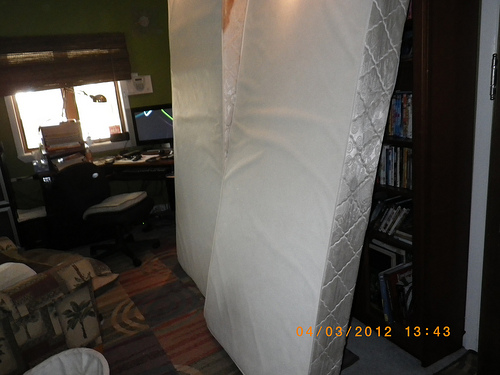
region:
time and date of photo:
[293, 325, 456, 340]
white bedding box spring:
[218, 0, 385, 314]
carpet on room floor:
[122, 297, 196, 367]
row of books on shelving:
[379, 146, 413, 186]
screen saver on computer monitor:
[132, 104, 175, 141]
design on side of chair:
[60, 296, 95, 345]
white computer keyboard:
[107, 163, 168, 178]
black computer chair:
[63, 162, 163, 274]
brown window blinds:
[0, 36, 132, 82]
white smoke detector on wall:
[125, 6, 160, 33]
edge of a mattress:
[362, 142, 372, 216]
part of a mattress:
[253, 212, 266, 247]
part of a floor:
[163, 307, 183, 348]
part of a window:
[98, 95, 113, 123]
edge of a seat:
[48, 250, 61, 294]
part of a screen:
[133, 113, 148, 121]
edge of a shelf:
[428, 250, 437, 289]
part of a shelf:
[386, 221, 408, 255]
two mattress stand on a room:
[155, 0, 410, 371]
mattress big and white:
[155, 0, 415, 371]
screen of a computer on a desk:
[117, 95, 172, 151]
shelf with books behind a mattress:
[350, 0, 480, 355]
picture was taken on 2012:
[211, 200, 498, 373]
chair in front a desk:
[2, 156, 64, 252]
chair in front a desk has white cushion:
[48, 156, 165, 271]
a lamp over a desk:
[54, 80, 114, 119]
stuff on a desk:
[97, 141, 150, 165]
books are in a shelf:
[374, 97, 413, 334]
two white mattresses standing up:
[110, 6, 447, 373]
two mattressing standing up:
[132, 25, 450, 371]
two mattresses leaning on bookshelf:
[121, 12, 497, 302]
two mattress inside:
[107, 23, 457, 373]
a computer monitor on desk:
[102, 90, 229, 184]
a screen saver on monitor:
[112, 91, 210, 163]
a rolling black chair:
[53, 145, 178, 277]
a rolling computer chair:
[37, 150, 183, 273]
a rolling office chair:
[44, 152, 174, 267]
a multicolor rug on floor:
[54, 222, 246, 373]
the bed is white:
[229, 182, 321, 267]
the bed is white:
[192, 167, 286, 241]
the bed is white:
[259, 202, 304, 266]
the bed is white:
[242, 154, 290, 219]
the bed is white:
[246, 135, 290, 193]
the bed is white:
[219, 134, 251, 174]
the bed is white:
[219, 121, 244, 155]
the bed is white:
[206, 125, 277, 227]